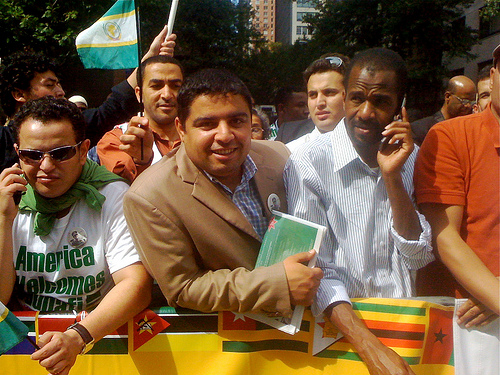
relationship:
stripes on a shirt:
[332, 184, 366, 255] [284, 122, 420, 297]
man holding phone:
[290, 38, 444, 373] [384, 88, 413, 150]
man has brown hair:
[122, 64, 333, 318] [174, 66, 256, 128]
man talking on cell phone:
[285, 51, 435, 375] [390, 92, 412, 143]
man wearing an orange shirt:
[413, 43, 498, 328] [413, 100, 498, 297]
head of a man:
[442, 75, 477, 115] [405, 73, 478, 145]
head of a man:
[170, 62, 255, 178] [122, 64, 333, 318]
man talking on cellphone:
[285, 51, 435, 375] [397, 96, 409, 147]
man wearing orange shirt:
[413, 43, 500, 332] [413, 100, 498, 297]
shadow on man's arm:
[409, 126, 451, 253] [373, 104, 437, 274]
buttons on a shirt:
[368, 190, 392, 300] [275, 119, 433, 320]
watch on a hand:
[74, 321, 94, 353] [30, 330, 75, 373]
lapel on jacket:
[171, 162, 258, 242] [119, 132, 296, 324]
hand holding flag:
[146, 20, 183, 60] [73, 0, 190, 92]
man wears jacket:
[122, 69, 296, 318] [144, 165, 226, 252]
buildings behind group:
[278, 7, 325, 43] [0, 23, 500, 375]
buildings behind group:
[247, 0, 278, 55] [0, 23, 500, 375]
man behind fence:
[2, 97, 150, 375] [140, 312, 224, 374]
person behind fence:
[142, 91, 318, 322] [140, 312, 224, 374]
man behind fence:
[285, 51, 435, 375] [140, 312, 224, 374]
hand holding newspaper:
[243, 208, 327, 333] [245, 218, 334, 294]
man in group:
[285, 51, 435, 375] [18, 23, 484, 338]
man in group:
[2, 97, 150, 375] [18, 23, 484, 338]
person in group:
[142, 91, 318, 322] [18, 23, 484, 338]